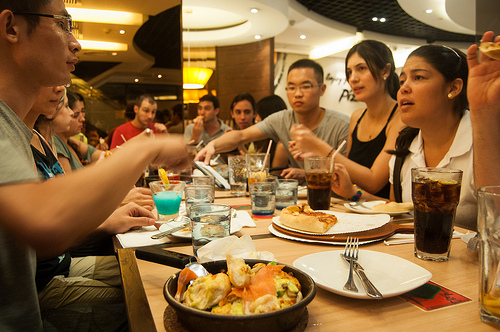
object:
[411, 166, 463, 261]
glass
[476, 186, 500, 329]
glass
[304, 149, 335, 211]
glass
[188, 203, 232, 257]
glass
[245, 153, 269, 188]
glass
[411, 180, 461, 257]
cola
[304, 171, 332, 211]
cola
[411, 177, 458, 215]
ice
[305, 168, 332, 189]
ice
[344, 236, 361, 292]
fork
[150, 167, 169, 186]
orange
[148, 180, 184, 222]
glass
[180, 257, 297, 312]
food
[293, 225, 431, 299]
plate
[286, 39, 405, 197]
woman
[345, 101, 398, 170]
tank top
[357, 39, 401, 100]
hair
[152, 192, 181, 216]
blue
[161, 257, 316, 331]
bowl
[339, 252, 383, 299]
knife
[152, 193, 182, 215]
liquid